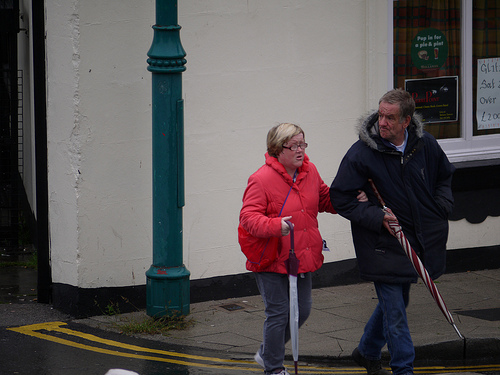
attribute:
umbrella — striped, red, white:
[364, 174, 479, 353]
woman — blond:
[247, 119, 334, 372]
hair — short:
[264, 122, 304, 166]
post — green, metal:
[147, 3, 192, 316]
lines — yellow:
[16, 313, 116, 359]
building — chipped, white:
[38, 1, 226, 289]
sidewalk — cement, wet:
[122, 299, 357, 351]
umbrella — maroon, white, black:
[283, 219, 306, 371]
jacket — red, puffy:
[227, 152, 340, 272]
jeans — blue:
[358, 276, 422, 368]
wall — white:
[67, 28, 131, 253]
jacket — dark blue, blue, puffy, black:
[324, 127, 461, 284]